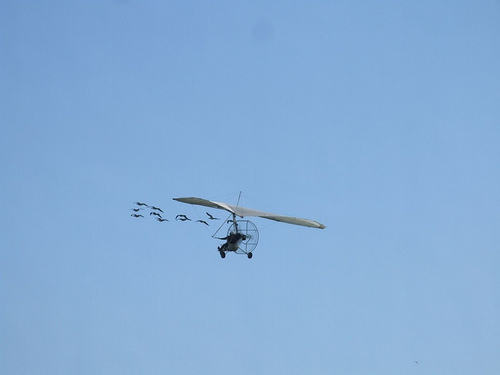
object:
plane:
[172, 190, 326, 259]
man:
[214, 231, 246, 251]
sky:
[0, 1, 499, 374]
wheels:
[247, 251, 252, 258]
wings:
[172, 196, 326, 229]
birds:
[131, 200, 236, 226]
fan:
[227, 219, 259, 254]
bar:
[237, 190, 243, 207]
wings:
[133, 201, 149, 208]